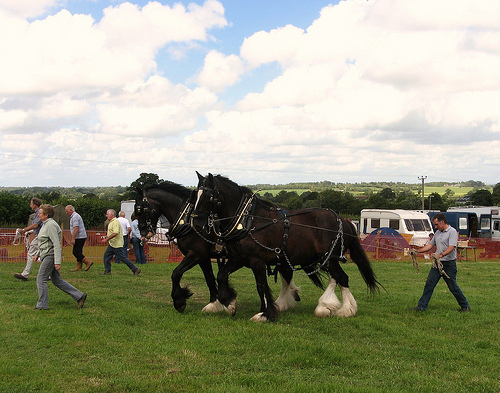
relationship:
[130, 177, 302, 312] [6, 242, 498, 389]
horse on grass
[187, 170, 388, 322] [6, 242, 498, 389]
horse on grass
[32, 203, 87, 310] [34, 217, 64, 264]
baseball player in shirt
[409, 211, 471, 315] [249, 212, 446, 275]
man holding reigns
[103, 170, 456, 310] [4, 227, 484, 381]
two horses on grass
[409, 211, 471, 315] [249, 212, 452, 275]
man holding reigns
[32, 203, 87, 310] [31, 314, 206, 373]
baseball player walking on grass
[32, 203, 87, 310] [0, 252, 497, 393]
baseball player running on grass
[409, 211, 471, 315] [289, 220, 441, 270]
man holding rope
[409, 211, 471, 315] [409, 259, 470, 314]
man wearing pants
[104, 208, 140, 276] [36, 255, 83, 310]
man wearing pants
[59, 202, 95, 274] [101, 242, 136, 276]
man wearing pants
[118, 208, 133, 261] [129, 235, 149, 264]
man wearing pants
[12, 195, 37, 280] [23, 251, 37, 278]
man wearing pants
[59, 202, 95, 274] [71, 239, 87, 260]
man wearing pants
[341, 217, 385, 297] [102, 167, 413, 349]
tail of horse